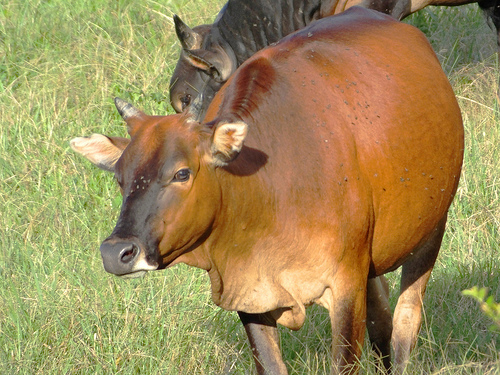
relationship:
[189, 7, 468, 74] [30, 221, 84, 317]
animal standing in grass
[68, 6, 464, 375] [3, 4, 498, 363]
animal in grass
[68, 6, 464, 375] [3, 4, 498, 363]
animal on grass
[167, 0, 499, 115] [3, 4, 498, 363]
animal on grass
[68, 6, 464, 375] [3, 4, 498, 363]
animal standing in grass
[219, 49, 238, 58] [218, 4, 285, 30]
top of carabaos black neck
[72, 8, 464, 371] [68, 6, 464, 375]
skin of a animal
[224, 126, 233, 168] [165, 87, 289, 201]
hair inside carabaoss ear